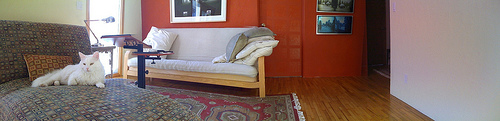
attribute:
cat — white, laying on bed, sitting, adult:
[28, 51, 108, 91]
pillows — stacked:
[211, 25, 280, 68]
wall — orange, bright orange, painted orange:
[141, 0, 370, 81]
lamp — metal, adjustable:
[83, 14, 116, 49]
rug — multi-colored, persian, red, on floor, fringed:
[135, 81, 308, 120]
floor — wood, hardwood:
[106, 74, 436, 120]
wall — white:
[388, 1, 499, 120]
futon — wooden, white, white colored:
[121, 26, 267, 101]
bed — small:
[0, 17, 205, 119]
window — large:
[90, 1, 123, 77]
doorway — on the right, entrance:
[366, 0, 391, 81]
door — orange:
[259, 1, 302, 79]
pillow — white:
[134, 25, 178, 61]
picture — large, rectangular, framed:
[169, 1, 230, 23]